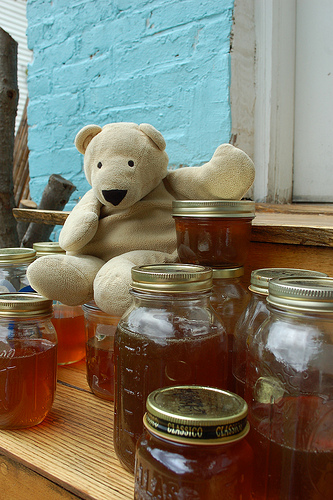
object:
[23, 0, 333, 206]
brick building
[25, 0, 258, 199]
brick wall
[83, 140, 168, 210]
face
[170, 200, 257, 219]
cap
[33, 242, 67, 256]
cap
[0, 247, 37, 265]
cap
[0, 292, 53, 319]
cap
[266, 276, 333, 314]
cap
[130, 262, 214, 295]
cap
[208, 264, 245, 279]
cap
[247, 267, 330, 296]
cap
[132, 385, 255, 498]
jar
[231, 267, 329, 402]
jar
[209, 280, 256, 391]
jar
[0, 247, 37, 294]
jar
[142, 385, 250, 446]
cap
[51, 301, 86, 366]
jar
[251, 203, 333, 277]
wood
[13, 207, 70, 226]
wood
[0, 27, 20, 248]
wood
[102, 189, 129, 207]
nose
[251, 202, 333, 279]
step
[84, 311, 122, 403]
jar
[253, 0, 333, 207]
door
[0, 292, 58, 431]
glass jar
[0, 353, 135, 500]
table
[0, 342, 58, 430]
liquid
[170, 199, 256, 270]
jar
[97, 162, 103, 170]
eye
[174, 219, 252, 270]
honey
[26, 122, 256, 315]
teddy bear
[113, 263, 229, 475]
honey jar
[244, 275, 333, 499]
honey jar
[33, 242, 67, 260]
jars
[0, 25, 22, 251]
tree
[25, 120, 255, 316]
stuffed animal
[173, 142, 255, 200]
arm